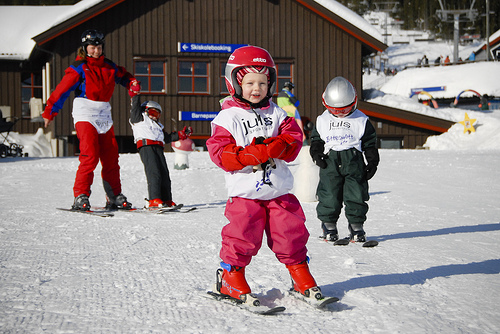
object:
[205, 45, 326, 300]
child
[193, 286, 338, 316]
skis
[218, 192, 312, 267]
snow pants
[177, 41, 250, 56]
sign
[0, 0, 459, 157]
building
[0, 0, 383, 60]
snow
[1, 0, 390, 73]
roof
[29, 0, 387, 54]
stripe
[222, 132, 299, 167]
mittens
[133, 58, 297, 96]
windows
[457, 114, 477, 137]
star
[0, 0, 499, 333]
snow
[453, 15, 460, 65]
pole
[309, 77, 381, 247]
skier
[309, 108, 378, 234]
suit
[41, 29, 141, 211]
mother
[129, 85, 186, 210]
child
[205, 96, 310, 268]
suit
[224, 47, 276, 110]
helmet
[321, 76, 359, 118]
helmet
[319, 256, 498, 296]
shadows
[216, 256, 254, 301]
ski boots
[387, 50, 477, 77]
people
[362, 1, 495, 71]
ski lift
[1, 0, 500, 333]
ground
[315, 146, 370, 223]
snow pants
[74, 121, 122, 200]
snow pants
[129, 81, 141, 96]
hand